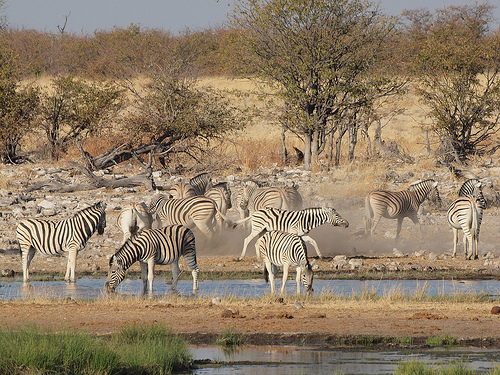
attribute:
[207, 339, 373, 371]
ground — swampy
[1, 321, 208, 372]
grass — tall, green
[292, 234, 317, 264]
mane — black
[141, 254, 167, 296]
leg — white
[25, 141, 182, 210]
tree — dead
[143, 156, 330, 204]
ground — rocky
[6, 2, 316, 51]
sky — gray, blue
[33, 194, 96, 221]
rocks — grey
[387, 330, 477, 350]
grass — small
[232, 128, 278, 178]
grass — brown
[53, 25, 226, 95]
trees — thick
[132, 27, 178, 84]
leaves — brown, green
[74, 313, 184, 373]
grass — green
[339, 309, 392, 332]
dirt — brown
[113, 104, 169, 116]
leaves — green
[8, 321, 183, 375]
grass —  long and green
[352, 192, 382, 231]
tail — white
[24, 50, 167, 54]
sky — dark blue